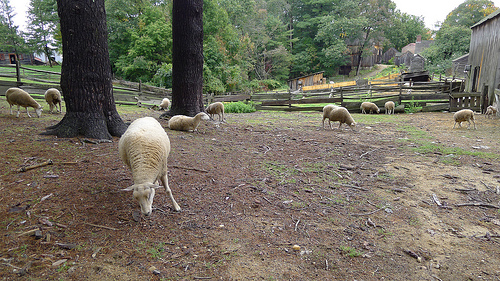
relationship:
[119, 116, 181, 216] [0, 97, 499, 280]
sheep in dirt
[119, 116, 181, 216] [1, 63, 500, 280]
sheep in a pen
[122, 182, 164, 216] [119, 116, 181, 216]
head of sheep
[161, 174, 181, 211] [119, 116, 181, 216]
leg of sheep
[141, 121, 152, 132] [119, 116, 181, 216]
wool on back of sheep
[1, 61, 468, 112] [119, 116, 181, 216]
fence surrounding sheep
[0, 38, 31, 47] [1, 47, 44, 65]
roof of house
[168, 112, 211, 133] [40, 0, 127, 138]
sheep laying in front of tree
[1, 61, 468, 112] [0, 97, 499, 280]
fence around dirt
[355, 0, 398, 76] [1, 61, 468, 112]
tree behind fence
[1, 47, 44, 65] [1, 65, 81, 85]
house on hill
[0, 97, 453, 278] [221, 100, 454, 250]
ground with little grass